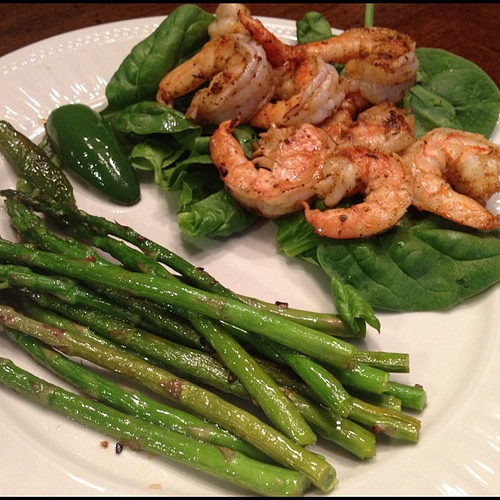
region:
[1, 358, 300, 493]
fresh whole green bean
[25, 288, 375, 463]
fresh whole green bean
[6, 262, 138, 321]
fresh whole green bean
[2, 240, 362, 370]
fresh whole green bean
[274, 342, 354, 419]
fresh whole green bean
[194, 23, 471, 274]
brown and cooked shrimp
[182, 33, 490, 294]
green lettuce under shrimp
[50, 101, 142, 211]
one pepper on plate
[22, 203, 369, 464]
large pile of asparagus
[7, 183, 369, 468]
green and brown asparagus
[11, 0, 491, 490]
plate on brown table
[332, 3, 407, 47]
green stems on lettuce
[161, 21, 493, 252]
brown and seasoned shrimp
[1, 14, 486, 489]
a plate on the table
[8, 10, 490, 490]
a plate of food on the table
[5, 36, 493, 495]
the plate is white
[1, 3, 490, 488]
the plate is round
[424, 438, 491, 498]
light on the plate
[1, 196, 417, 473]
many sticks of asparagus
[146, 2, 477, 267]
shrimp on the plate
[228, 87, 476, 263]
the shrimp are pink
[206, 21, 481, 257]
the shrimp are fried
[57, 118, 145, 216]
light reflecting off of the vegetable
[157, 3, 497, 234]
cooked shrimps on a plate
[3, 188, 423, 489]
asparagus baked in oil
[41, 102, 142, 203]
jalapenos pepper on a white plate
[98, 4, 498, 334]
raw spinach salad on a plate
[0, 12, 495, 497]
a white plate on a wooden surface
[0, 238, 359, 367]
a stem of asparagus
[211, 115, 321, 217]
a pink cooked shrimp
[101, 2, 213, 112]
a green spinach leaf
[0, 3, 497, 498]
a plate with shrimps and veggies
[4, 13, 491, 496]
a plate with shrimps, asparagus and spinach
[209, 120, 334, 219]
a pink succulent shrimp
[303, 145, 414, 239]
a pink succulent shrimp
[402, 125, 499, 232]
a pink succulent shrimp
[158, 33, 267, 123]
a sauteed jumbo shrimp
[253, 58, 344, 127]
a sauteed jumbo shrimp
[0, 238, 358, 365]
a stock of roasted asparagus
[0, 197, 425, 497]
a pile of roasted asparagus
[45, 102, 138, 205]
a ripe jalapeno pepper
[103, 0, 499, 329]
shrimp resting on a bed of spinach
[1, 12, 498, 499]
a white plate filled with food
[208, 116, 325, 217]
The shrimp is grilled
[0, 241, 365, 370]
The asparaghus on the plate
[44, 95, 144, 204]
The pepper is green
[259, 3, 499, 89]
The wooden table in the corner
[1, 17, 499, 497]
The white plate under the food